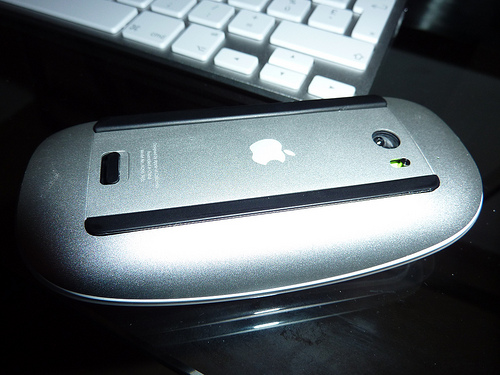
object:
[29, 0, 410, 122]
keyboard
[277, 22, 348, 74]
key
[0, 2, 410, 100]
computer keyboard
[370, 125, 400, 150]
sensor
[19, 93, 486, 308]
mouse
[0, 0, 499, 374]
table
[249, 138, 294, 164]
apple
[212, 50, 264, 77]
key